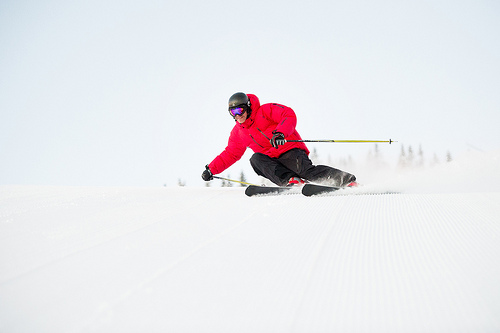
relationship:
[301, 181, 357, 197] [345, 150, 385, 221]
ski kicking up snow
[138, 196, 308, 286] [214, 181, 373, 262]
snow covering slope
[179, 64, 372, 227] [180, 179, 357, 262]
man on snow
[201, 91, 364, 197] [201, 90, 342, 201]
skier wearing gear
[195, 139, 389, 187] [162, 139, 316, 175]
poles in hands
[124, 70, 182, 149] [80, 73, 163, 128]
clouds in sky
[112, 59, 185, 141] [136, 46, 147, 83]
clouds in sky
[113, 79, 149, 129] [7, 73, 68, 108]
clouds in sky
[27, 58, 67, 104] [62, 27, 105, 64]
clouds in sky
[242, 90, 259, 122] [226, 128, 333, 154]
hood on jacket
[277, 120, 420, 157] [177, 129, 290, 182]
poles in hands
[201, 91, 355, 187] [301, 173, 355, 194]
skier wearing ski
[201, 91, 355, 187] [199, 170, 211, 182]
skier wearing glove